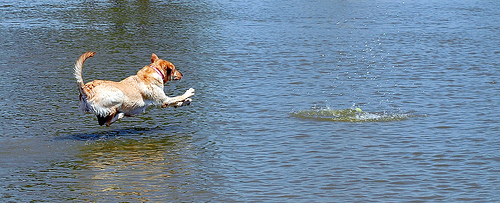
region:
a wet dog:
[70, 47, 198, 121]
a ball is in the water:
[287, 86, 414, 129]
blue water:
[209, 26, 371, 81]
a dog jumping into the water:
[43, 34, 209, 143]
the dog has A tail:
[60, 46, 107, 100]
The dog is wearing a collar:
[140, 56, 185, 91]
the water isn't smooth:
[176, 23, 443, 148]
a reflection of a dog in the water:
[54, 122, 224, 201]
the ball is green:
[285, 89, 400, 130]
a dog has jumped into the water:
[71, 36, 220, 201]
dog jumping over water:
[36, 35, 238, 135]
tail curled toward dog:
[60, 40, 195, 142]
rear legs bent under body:
[60, 41, 200, 131]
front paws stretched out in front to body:
[60, 45, 205, 130]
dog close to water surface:
[65, 41, 202, 141]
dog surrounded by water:
[26, 10, 236, 180]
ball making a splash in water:
[275, 35, 420, 140]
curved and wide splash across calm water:
[265, 30, 420, 140]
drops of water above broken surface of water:
[291, 30, 416, 140]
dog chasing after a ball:
[51, 35, 424, 166]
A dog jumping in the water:
[35, 44, 230, 144]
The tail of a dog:
[57, 44, 105, 88]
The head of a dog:
[146, 50, 181, 84]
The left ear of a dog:
[143, 51, 163, 62]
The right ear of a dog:
[161, 59, 174, 74]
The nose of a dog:
[174, 62, 184, 82]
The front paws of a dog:
[171, 87, 218, 113]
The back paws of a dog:
[88, 105, 126, 125]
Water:
[193, 133, 324, 197]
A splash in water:
[262, 90, 436, 151]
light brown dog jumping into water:
[71, 50, 203, 127]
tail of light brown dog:
[71, 49, 95, 94]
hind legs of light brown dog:
[89, 88, 126, 125]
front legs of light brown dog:
[155, 89, 195, 108]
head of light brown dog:
[150, 53, 181, 84]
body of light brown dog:
[101, 76, 157, 113]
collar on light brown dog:
[148, 63, 166, 82]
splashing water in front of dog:
[293, 100, 418, 130]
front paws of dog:
[186, 87, 196, 107]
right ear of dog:
[166, 61, 173, 72]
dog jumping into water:
[72, 42, 208, 120]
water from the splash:
[314, 20, 426, 120]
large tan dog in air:
[75, 30, 205, 122]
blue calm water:
[49, 122, 497, 189]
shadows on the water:
[95, 7, 202, 56]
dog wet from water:
[88, 48, 211, 142]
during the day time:
[236, 9, 469, 91]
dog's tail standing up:
[77, 40, 116, 111]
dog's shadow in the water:
[89, 130, 201, 200]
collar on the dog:
[146, 62, 168, 87]